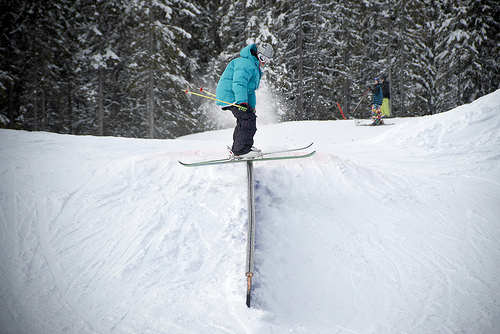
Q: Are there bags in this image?
A: No, there are no bags.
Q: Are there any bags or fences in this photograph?
A: No, there are no bags or fences.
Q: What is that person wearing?
A: The person is wearing a jacket.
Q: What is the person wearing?
A: The person is wearing a jacket.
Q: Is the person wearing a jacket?
A: Yes, the person is wearing a jacket.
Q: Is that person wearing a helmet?
A: No, the person is wearing a jacket.